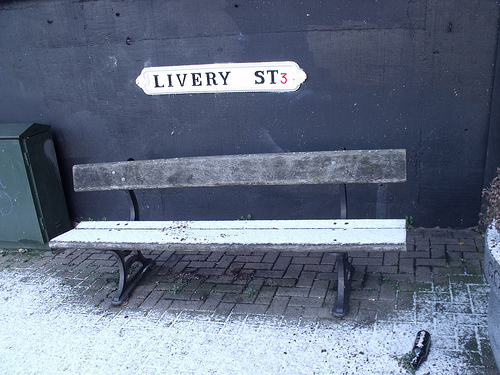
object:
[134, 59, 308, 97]
sign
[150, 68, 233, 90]
lettering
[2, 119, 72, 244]
trashcan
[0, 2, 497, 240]
wall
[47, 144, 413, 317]
bench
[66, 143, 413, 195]
backrest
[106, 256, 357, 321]
feet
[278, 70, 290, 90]
number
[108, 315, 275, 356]
paint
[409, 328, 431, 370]
bottle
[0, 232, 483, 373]
ground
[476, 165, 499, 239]
plant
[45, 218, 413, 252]
seat